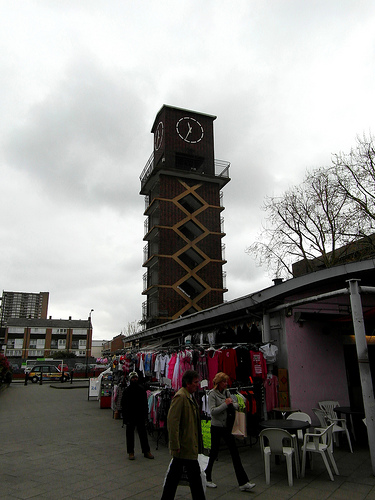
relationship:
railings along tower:
[155, 143, 234, 177] [134, 98, 232, 328]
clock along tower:
[157, 108, 206, 146] [126, 98, 263, 384]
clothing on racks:
[133, 349, 195, 384] [134, 340, 248, 352]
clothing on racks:
[143, 387, 174, 424] [127, 377, 180, 392]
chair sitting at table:
[254, 426, 299, 486] [261, 413, 310, 468]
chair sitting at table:
[299, 419, 341, 483] [261, 413, 310, 468]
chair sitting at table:
[282, 408, 311, 441] [261, 413, 310, 468]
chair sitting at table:
[311, 406, 354, 454] [332, 401, 360, 439]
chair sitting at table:
[318, 398, 345, 422] [332, 401, 360, 439]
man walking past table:
[160, 369, 205, 498] [254, 417, 312, 432]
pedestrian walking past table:
[204, 371, 255, 492] [254, 417, 312, 432]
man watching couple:
[116, 370, 156, 461] [160, 368, 257, 498]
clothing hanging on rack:
[248, 343, 269, 383] [110, 323, 281, 422]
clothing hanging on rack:
[218, 343, 238, 379] [110, 323, 281, 422]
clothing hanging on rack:
[203, 345, 220, 387] [110, 323, 281, 422]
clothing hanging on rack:
[165, 347, 176, 380] [110, 323, 281, 422]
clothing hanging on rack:
[150, 350, 168, 379] [110, 323, 281, 422]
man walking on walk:
[160, 369, 205, 498] [1, 379, 374, 497]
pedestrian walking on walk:
[204, 371, 255, 492] [1, 379, 374, 497]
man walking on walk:
[120, 372, 155, 461] [1, 379, 374, 497]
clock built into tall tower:
[175, 117, 205, 145] [138, 104, 230, 330]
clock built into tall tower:
[153, 120, 163, 153] [138, 104, 230, 330]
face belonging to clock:
[177, 117, 202, 140] [172, 115, 204, 147]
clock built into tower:
[142, 120, 167, 151] [134, 98, 232, 328]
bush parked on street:
[26, 357, 65, 381] [2, 369, 97, 390]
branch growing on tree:
[252, 238, 294, 275] [245, 132, 363, 275]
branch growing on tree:
[274, 206, 304, 245] [245, 132, 363, 275]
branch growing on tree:
[274, 224, 303, 247] [245, 132, 363, 275]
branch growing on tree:
[300, 203, 325, 244] [245, 132, 363, 275]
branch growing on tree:
[308, 177, 326, 211] [245, 132, 363, 275]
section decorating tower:
[175, 189, 205, 214] [99, 98, 273, 271]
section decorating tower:
[171, 214, 209, 242] [99, 98, 273, 271]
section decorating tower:
[171, 242, 208, 269] [99, 98, 273, 271]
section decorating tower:
[174, 273, 209, 303] [99, 98, 273, 271]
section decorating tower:
[170, 302, 208, 319] [99, 98, 273, 271]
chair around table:
[258, 427, 300, 487] [246, 412, 312, 447]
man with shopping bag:
[160, 369, 205, 498] [161, 452, 210, 494]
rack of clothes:
[94, 341, 293, 396] [128, 352, 267, 384]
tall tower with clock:
[135, 95, 251, 347] [172, 109, 211, 147]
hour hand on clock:
[187, 120, 192, 131] [172, 113, 207, 145]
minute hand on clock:
[182, 129, 191, 138] [172, 113, 207, 145]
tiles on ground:
[70, 431, 127, 481] [38, 347, 320, 496]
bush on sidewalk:
[46, 349, 80, 361] [1, 383, 374, 498]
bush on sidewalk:
[2, 366, 12, 383] [1, 383, 374, 498]